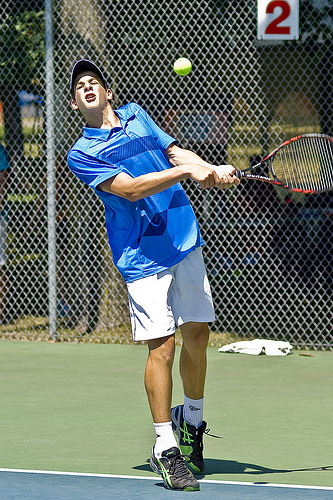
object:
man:
[66, 59, 240, 491]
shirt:
[66, 103, 205, 288]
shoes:
[170, 395, 206, 480]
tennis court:
[0, 340, 332, 498]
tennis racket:
[196, 132, 333, 196]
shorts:
[122, 241, 215, 342]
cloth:
[217, 336, 293, 360]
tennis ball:
[172, 56, 193, 78]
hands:
[188, 164, 217, 188]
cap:
[68, 58, 108, 96]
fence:
[0, 0, 332, 351]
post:
[45, 2, 57, 338]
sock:
[151, 419, 177, 456]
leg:
[129, 274, 175, 435]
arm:
[65, 151, 194, 204]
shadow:
[129, 455, 333, 480]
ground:
[0, 336, 332, 499]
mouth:
[84, 93, 96, 102]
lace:
[166, 452, 192, 473]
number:
[256, 0, 300, 41]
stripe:
[106, 135, 159, 166]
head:
[69, 58, 114, 114]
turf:
[0, 334, 332, 499]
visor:
[66, 60, 105, 91]